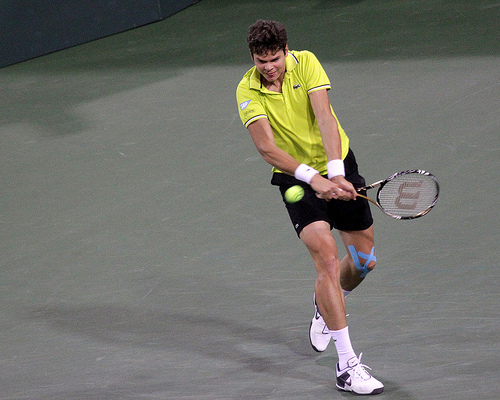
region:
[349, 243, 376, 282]
the blue tape on his knee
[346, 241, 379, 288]
his hurt bent knee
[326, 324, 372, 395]
his white shoes and socks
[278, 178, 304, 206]
the green tennis ball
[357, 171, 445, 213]
the tennis racket in his hand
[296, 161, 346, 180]
the white wrist bands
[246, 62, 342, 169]
his bright yellow shirt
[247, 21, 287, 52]
his curly brown hair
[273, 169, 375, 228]
his brown athletic shorts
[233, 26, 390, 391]
the man playing tennis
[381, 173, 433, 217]
the Wilson logo on tennis racket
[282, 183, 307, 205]
the yellow tennis ball in air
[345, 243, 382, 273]
a blue marking on man's knee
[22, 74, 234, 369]
part of the gray floor on tennis court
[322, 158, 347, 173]
a wrist band on man's hand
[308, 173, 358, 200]
both of man's hands gripping tennis racket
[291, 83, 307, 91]
a logo on the man's yellow shirt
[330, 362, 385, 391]
black and white shoe on man's foot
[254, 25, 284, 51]
black hair on tennis player's head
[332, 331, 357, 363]
a white sock on tennis player's leg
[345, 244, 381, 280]
blue bandages on knee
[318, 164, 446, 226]
man holding Wilson tennis racket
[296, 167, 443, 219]
man holding racket in both hands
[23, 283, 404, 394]
shadow of man on concrete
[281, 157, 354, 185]
white wristbands on both wrists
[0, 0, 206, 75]
bluish gray tarp behind court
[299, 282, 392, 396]
man in white and black sneakers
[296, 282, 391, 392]
right leg in front of left leg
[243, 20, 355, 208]
man looking at tennis ball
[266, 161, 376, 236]
black shorts with small white logo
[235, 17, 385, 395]
Man playing tennis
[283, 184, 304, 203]
Tennis ball in the air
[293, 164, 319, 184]
Bracer on the man's right wrist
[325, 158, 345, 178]
Bracer on the man's left hand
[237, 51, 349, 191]
Green shirt on the man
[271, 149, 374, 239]
Black shorts on the man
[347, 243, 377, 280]
Tapes on the man's knee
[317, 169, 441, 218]
Racket in the man's hands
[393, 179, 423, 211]
Letter on the racket web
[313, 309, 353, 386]
Nike logos on the man's shoes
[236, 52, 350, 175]
a yellow short sleeve tennis shirt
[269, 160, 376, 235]
a black pair of tennis shorts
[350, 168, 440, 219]
a black tennis racquet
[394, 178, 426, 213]
a red "W" printed on face of tennis racquet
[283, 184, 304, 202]
a green tennis ball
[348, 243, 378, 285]
strips of blue tape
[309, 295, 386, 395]
a pair of white nike tennis shoes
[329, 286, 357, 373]
a pair of white socks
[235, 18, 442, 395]
a tennis player swinging at a tennis ball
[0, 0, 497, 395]
a dark green tennis court